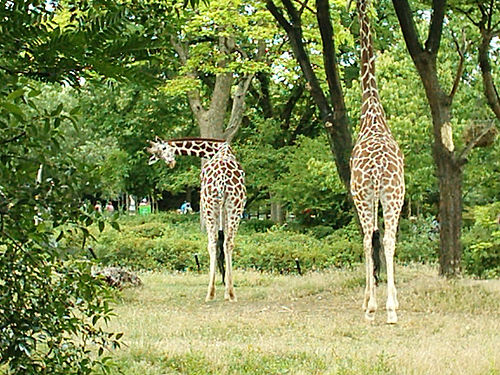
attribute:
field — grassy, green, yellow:
[5, 213, 498, 370]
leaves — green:
[17, 69, 122, 221]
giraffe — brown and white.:
[132, 119, 252, 308]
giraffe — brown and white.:
[330, 1, 408, 328]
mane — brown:
[163, 132, 228, 144]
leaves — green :
[112, 101, 185, 116]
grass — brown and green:
[82, 245, 492, 374]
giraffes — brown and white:
[142, 62, 402, 302]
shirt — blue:
[182, 205, 186, 209]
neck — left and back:
[158, 130, 226, 167]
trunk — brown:
[394, 2, 464, 273]